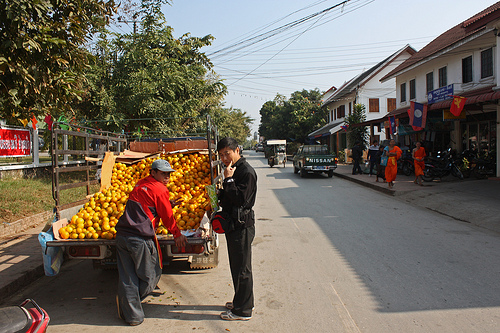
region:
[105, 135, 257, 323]
Two men standing next to a truck.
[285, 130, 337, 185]
A pick-up truck on the street.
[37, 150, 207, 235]
Oranges in the back of the truck.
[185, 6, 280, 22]
The sky is blue.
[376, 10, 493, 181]
A building next to the street.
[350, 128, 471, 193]
People on the sidewalk.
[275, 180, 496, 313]
The building is casting a shadow on the street.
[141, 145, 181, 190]
The man is wearing a hat.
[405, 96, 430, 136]
A flag hanging from the building.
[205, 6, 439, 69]
Power lines above the street.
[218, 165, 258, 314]
the man is in black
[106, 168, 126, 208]
the oranges are ripe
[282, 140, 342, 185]
the make of car is nissan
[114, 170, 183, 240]
the top is red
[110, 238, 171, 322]
the pants are gray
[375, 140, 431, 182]
the have red clothes on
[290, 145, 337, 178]
the car is green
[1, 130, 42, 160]
the sign is red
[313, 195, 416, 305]
there is shadow on the ground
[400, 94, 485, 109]
the awning has flags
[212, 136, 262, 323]
A man with a black outfit.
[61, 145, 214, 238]
Fruits in the back of the truck.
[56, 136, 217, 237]
Oranges on the back of a small truck.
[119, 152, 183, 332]
A person leaning on the back of the truck.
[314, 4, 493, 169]
Buildings on the side of the road.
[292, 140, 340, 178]
Green truck on the side of the pavement.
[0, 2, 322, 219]
Trees lined up on both sides of the road.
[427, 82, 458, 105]
Blue poster on the canopy of building.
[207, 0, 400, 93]
Electric wires crossing on top of the buildings.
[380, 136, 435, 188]
People walking on the side of the road.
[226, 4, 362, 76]
the wires in the sky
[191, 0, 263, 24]
the clear blue sky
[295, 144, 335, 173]
the green nissan truck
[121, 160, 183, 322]
the man in standing in front of the oranges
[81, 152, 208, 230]
the pile of oranges in the bed of the truck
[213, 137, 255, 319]
the man all dressed in black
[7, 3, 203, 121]
the trees to the left of the oranges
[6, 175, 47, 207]
the grass patch to the left of the oranges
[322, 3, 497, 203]
the buildings to the right of the oranges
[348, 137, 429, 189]
the people on the sidewalk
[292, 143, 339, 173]
Green Nissan Pickup Truck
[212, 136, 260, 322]
Guy wearing all black standing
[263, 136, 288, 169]
white bicycle cart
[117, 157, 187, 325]
Man selling fruit out of the back of a truck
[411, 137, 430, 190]
Lady in red dress walking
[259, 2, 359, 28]
Many power lines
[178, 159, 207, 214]
Large amount of fruit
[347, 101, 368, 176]
Tall green bush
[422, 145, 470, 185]
Parked motorcycle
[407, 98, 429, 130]
Hanging Flag